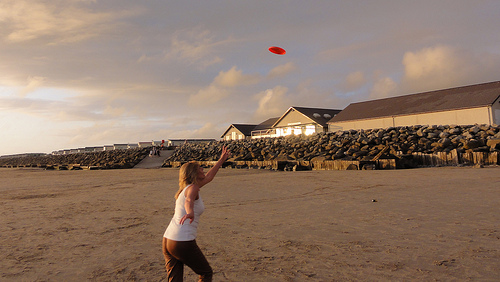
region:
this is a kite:
[268, 41, 288, 61]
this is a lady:
[159, 147, 234, 280]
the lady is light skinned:
[186, 198, 195, 206]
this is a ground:
[276, 192, 456, 264]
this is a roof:
[359, 100, 426, 109]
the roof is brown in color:
[362, 102, 414, 111]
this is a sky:
[64, 54, 129, 90]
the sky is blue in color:
[217, 3, 244, 21]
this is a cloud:
[409, 62, 438, 73]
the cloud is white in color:
[413, 60, 433, 72]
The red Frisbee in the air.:
[262, 43, 290, 55]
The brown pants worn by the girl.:
[157, 237, 217, 280]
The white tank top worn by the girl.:
[166, 182, 203, 244]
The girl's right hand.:
[180, 212, 197, 224]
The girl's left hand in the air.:
[218, 145, 233, 157]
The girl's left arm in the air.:
[201, 159, 229, 183]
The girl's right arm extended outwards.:
[185, 185, 197, 214]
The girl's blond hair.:
[176, 159, 202, 191]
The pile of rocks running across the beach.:
[8, 121, 492, 176]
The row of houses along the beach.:
[42, 105, 496, 154]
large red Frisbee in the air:
[235, 33, 331, 71]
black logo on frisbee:
[270, 38, 287, 55]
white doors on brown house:
[278, 120, 317, 132]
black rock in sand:
[354, 187, 416, 219]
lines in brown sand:
[244, 234, 376, 273]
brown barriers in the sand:
[310, 148, 487, 194]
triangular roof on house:
[284, 99, 328, 129]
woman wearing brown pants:
[139, 219, 219, 278]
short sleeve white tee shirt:
[117, 171, 217, 250]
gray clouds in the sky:
[47, 19, 224, 114]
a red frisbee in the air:
[253, 30, 295, 75]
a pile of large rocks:
[270, 139, 391, 163]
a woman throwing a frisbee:
[159, 117, 247, 275]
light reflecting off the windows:
[276, 121, 296, 134]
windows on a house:
[225, 129, 242, 141]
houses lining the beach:
[56, 140, 178, 151]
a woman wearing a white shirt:
[166, 149, 246, 277]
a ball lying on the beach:
[365, 189, 394, 208]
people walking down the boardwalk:
[146, 136, 165, 157]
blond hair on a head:
[180, 167, 190, 179]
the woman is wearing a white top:
[158, 181, 208, 241]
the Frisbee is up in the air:
[267, 43, 286, 55]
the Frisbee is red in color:
[267, 43, 286, 56]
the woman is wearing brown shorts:
[156, 236, 214, 280]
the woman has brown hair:
[172, 158, 203, 199]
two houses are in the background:
[218, 106, 340, 152]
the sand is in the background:
[5, 164, 498, 279]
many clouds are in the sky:
[2, 0, 499, 147]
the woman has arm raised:
[192, 146, 237, 186]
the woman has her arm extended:
[182, 183, 198, 223]